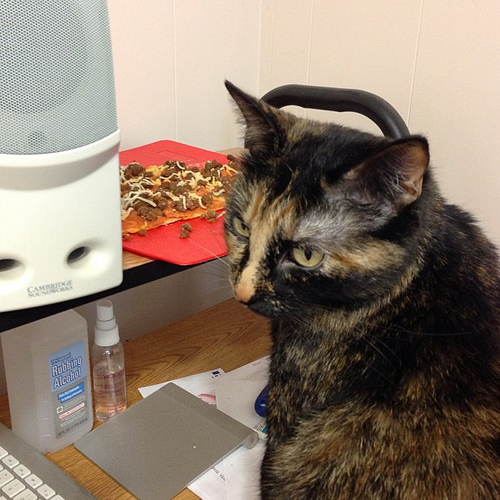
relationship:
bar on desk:
[260, 83, 413, 139] [45, 146, 270, 499]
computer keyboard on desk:
[1, 424, 98, 498] [1, 141, 289, 498]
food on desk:
[113, 129, 235, 251] [4, 122, 440, 495]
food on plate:
[119, 154, 235, 241] [119, 136, 227, 266]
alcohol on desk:
[0, 320, 100, 450] [0, 277, 457, 489]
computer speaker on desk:
[0, 2, 123, 310] [2, 83, 410, 498]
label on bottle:
[47, 342, 92, 431] [0, 308, 99, 451]